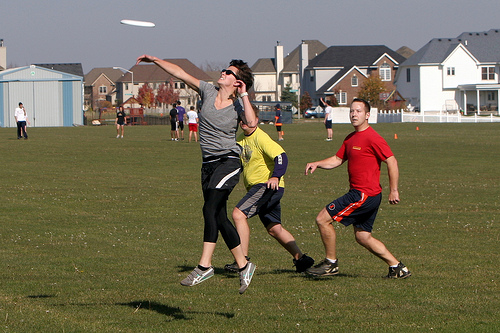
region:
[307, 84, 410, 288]
man wearing red shirt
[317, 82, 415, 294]
man wearing blue and red shorts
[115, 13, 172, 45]
white frisbee in the air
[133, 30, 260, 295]
woman wearing a gray shirt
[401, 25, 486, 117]
white house with gray roof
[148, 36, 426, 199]
people on the grass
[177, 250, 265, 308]
shoes of the girl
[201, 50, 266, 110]
head of the lady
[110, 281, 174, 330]
shadow on the ground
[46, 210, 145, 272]
green grass on ground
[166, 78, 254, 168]
gray shirt on lady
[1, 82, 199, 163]
people in the distance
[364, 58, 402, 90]
window on the house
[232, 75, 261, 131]
this is a person's hand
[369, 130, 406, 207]
this is a person's hand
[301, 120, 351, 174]
this is a person's hand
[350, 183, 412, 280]
this is a person's leg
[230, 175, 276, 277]
this is a person's leg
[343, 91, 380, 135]
this is a person's head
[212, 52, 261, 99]
this is a person's head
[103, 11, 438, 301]
people playing frisbee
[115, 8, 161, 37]
Frisbee is color wite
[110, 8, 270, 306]
woman trowing a frisbee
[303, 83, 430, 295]
the man is running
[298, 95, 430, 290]
man has red shirt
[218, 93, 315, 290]
a person with yellow top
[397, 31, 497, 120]
white house with black roof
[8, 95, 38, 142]
man wearing white shirt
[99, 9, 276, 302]
woman is jumping hight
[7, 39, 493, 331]
people playing in a field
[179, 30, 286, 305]
a person on a field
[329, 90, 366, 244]
a person on a field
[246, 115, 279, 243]
a person on a field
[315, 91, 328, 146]
a person on a field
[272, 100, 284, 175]
a person on a field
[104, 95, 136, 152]
a person on a field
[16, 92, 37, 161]
a person on a field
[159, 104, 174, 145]
a person on a field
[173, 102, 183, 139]
a person on a field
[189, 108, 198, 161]
a person on a field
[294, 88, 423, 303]
man wearing red shirt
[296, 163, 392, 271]
man wearing black shorts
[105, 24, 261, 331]
lady reaching for frisbie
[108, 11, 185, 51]
white frisbie in the air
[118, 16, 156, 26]
a white thrown frisbee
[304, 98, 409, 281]
a guy wearing a red shirt with black shorts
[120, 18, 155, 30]
the frisbee is in the air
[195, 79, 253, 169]
the woman is wearing a t shirt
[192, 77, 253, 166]
the shirt is grey in color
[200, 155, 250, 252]
the woman is wearing black pants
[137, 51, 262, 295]
the woman is in the air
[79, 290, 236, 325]
a shadow is on the ground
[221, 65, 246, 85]
the woman is wearing glasses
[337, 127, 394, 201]
the man is wearing a short sleeve shirt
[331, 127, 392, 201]
the shirt is red in color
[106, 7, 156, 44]
The white disc in the air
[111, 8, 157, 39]
A white disc in the air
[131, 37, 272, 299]
the woman wearing glasses